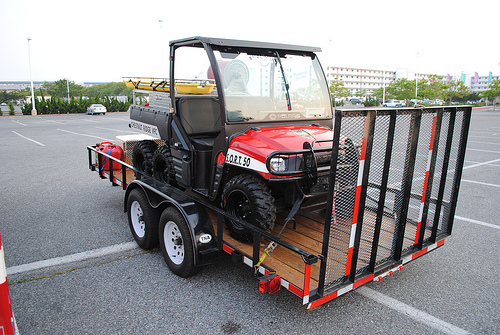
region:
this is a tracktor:
[74, 33, 475, 315]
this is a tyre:
[157, 206, 205, 281]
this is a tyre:
[120, 177, 162, 251]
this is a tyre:
[125, 135, 162, 186]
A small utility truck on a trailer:
[138, 31, 352, 223]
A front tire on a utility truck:
[221, 174, 272, 244]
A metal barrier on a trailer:
[316, 100, 468, 275]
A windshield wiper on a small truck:
[267, 52, 296, 113]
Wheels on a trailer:
[123, 193, 202, 275]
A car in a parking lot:
[85, 100, 110, 116]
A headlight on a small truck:
[269, 151, 291, 176]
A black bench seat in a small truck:
[181, 93, 276, 135]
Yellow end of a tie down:
[251, 250, 266, 279]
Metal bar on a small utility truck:
[265, 145, 364, 167]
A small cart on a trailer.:
[126, 36, 366, 247]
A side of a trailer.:
[307, 101, 474, 313]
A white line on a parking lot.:
[354, 286, 474, 333]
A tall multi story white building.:
[299, 63, 397, 112]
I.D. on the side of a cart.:
[221, 145, 253, 168]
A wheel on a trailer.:
[159, 207, 205, 272]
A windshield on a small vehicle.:
[211, 44, 333, 121]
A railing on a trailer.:
[84, 145, 318, 299]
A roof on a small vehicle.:
[164, 35, 325, 61]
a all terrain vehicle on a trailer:
[83, 34, 475, 313]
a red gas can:
[94, 137, 120, 174]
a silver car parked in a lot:
[86, 100, 108, 115]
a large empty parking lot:
[369, 101, 494, 186]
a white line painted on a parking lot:
[10, 237, 122, 284]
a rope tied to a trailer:
[253, 189, 308, 275]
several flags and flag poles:
[411, 72, 496, 103]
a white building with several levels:
[332, 63, 403, 97]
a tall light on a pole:
[25, 32, 37, 120]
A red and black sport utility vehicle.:
[129, 34, 365, 246]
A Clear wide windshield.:
[211, 44, 332, 124]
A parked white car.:
[83, 104, 106, 116]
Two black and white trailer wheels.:
[121, 185, 195, 277]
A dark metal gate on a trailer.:
[317, 107, 474, 301]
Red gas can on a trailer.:
[95, 142, 124, 172]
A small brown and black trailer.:
[87, 102, 474, 307]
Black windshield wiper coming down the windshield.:
[273, 50, 293, 110]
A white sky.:
[2, 1, 499, 75]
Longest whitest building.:
[323, 64, 397, 97]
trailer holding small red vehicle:
[78, 28, 475, 311]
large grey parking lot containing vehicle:
[13, 100, 485, 327]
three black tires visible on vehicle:
[128, 135, 278, 240]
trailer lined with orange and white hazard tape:
[86, 85, 478, 299]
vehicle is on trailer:
[128, 33, 368, 243]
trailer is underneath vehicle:
[87, 100, 472, 315]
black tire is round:
[215, 174, 275, 245]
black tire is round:
[149, 146, 174, 191]